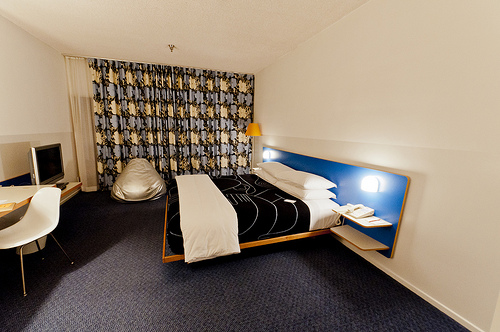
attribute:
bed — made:
[161, 144, 411, 263]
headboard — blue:
[261, 144, 412, 257]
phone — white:
[334, 203, 375, 228]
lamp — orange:
[244, 122, 265, 170]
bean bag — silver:
[112, 157, 168, 201]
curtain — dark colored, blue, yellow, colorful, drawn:
[87, 60, 255, 191]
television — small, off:
[32, 143, 66, 188]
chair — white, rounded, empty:
[0, 187, 75, 300]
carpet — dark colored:
[1, 193, 464, 330]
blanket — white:
[175, 174, 241, 263]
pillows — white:
[288, 171, 339, 200]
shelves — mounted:
[331, 204, 392, 253]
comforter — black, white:
[166, 175, 309, 249]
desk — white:
[0, 183, 56, 228]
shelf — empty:
[331, 225, 391, 252]